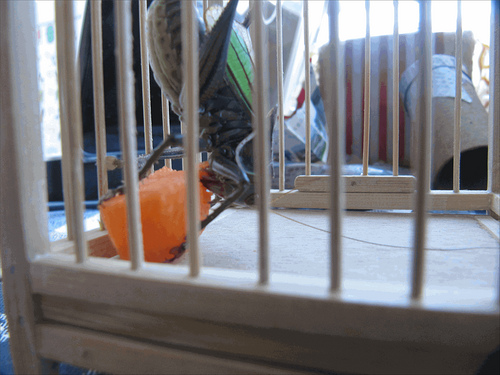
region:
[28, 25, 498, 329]
The cage is white.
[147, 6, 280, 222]
Bug in the cage.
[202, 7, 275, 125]
The wings are green.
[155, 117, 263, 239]
The bug is eating.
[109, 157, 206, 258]
The food is orange.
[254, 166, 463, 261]
The antenna are long.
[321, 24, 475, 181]
Chair in the background.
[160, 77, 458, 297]
The bars are white.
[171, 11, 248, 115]
The legs are bent.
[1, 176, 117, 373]
The floor is blue.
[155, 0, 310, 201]
A bug in a cage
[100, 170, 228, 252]
A piece of furit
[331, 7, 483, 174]
A chair in the back ground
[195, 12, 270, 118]
A green wing on a bug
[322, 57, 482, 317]
A white cage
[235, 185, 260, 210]
A eye on a bug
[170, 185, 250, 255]
A leg on a bug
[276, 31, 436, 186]
Door on a cage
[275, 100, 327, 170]
A paper lying on a chair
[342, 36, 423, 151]
Strips on a chair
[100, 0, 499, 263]
bug is upside down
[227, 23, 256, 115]
bug has green wing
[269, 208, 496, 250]
bug has long antennae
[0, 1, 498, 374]
cage is light wood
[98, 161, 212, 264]
bug is eating fruit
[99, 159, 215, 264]
bug is holding fruit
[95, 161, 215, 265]
fruit is sliced in cube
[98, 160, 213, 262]
fruit cube is orange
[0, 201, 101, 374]
blue floor under cage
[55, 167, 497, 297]
fruit is on cage bottom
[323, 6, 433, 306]
brown wooden cage bars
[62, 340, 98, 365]
small screw in wooden cage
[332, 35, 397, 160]
red and white striped chair back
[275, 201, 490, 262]
long antenna on insect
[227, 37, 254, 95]
green wing on insect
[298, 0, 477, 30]
light shining through window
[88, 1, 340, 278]
insect in cage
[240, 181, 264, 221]
black eye on head of insect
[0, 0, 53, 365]
brown wooden cage frame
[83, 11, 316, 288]
insect eating piece of orange food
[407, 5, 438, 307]
This is a wooden rod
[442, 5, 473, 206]
This is a wooden rod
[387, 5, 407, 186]
This is a wooden rod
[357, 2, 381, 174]
This is a wooden rod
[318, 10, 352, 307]
This is a wooden rod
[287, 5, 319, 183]
This is a wooden rod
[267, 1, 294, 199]
This is a wooden rod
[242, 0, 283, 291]
This is a wooden rod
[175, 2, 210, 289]
This is a wooden rod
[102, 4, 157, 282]
This is a wooden rod